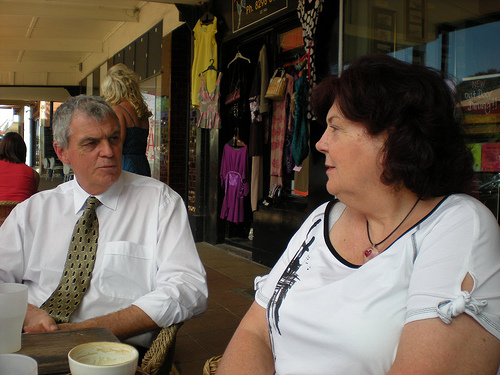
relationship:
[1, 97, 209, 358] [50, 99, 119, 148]
man has hair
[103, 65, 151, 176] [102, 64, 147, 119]
woman has hair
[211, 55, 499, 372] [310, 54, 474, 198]
woman has hair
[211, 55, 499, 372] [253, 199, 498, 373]
woman wearing shirt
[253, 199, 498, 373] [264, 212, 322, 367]
shirt has design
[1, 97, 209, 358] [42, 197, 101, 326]
man wearing tie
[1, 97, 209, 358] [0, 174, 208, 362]
man wearing shirt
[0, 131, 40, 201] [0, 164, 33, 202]
woman wearing shirt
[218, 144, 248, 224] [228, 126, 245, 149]
shirt on hanger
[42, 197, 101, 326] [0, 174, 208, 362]
tie on shirt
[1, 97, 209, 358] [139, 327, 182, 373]
man in chair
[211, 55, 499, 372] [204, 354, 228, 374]
woman in chair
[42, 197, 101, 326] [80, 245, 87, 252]
tie has spots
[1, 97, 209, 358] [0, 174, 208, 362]
man has shirt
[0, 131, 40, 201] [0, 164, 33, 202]
woman has shirt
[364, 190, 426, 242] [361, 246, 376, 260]
necklace has pendant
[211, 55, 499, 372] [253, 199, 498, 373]
woman has shirt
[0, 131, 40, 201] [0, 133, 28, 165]
woman has hair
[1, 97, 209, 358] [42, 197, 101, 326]
man has tie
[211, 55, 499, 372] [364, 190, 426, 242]
woman has necklace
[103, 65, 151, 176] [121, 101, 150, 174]
woman wearing dress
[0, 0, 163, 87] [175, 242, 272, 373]
roof over sidewalk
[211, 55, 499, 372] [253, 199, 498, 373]
woman in shirt